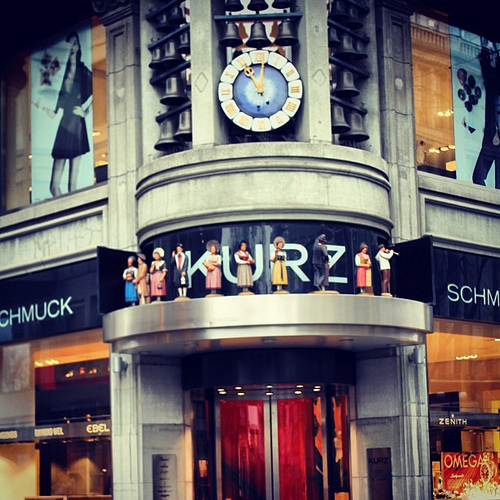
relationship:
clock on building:
[203, 38, 311, 148] [32, 297, 472, 481]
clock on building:
[215, 49, 304, 132] [41, 62, 451, 313]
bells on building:
[129, 55, 198, 168] [60, 203, 480, 462]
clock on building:
[215, 49, 304, 132] [66, 185, 440, 449]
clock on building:
[215, 49, 304, 132] [134, 30, 478, 230]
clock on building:
[215, 49, 304, 132] [75, 93, 449, 339]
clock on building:
[215, 49, 304, 132] [101, 75, 406, 285]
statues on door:
[104, 232, 406, 302] [166, 316, 373, 489]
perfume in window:
[434, 435, 482, 486] [411, 324, 481, 451]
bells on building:
[140, 47, 202, 151] [69, 50, 432, 252]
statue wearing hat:
[137, 235, 183, 305] [148, 234, 170, 264]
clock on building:
[215, 49, 304, 132] [101, 41, 417, 218]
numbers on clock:
[205, 52, 243, 118] [202, 42, 304, 130]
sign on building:
[17, 256, 114, 349] [15, 208, 451, 478]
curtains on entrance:
[214, 369, 320, 490] [209, 356, 346, 469]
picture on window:
[23, 32, 102, 202] [18, 32, 111, 198]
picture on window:
[6, 256, 459, 500] [16, 285, 233, 484]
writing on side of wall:
[24, 264, 104, 352] [11, 409, 54, 500]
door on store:
[215, 389, 347, 489] [8, 23, 478, 493]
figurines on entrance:
[115, 239, 392, 310] [94, 297, 434, 485]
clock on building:
[215, 49, 304, 132] [4, 11, 462, 463]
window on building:
[434, 316, 484, 479] [4, 11, 462, 463]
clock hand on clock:
[253, 51, 265, 94] [215, 49, 304, 132]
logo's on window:
[2, 297, 75, 332] [6, 342, 484, 492]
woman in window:
[451, 420, 481, 458] [434, 340, 484, 488]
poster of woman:
[432, 443, 484, 489] [451, 420, 481, 458]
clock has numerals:
[215, 49, 304, 132] [281, 99, 300, 113]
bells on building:
[150, 5, 370, 143] [4, 11, 462, 463]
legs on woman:
[32, 151, 97, 189] [36, 38, 102, 190]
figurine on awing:
[314, 230, 334, 292] [107, 223, 417, 308]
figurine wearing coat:
[314, 230, 334, 292] [311, 244, 333, 288]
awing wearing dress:
[111, 237, 411, 294] [268, 246, 288, 283]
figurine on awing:
[268, 232, 291, 290] [111, 237, 411, 294]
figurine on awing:
[119, 256, 140, 303] [113, 227, 406, 304]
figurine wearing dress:
[119, 256, 140, 303] [118, 269, 138, 304]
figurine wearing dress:
[230, 238, 258, 294] [234, 254, 259, 290]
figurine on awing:
[230, 238, 258, 294] [114, 220, 412, 300]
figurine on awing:
[136, 253, 160, 300] [106, 233, 406, 293]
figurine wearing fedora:
[136, 253, 160, 300] [136, 248, 146, 256]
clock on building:
[215, 49, 304, 132] [7, 15, 484, 495]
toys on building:
[217, 9, 297, 53] [4, 11, 462, 463]